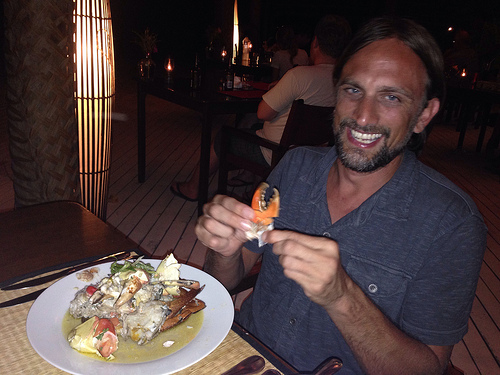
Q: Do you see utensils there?
A: Yes, there are utensils.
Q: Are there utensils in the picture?
A: Yes, there are utensils.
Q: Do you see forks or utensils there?
A: Yes, there are utensils.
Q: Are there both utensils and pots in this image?
A: No, there are utensils but no pots.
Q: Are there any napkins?
A: No, there are no napkins.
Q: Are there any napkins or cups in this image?
A: No, there are no napkins or cups.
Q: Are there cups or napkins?
A: No, there are no napkins or cups.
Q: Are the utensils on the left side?
A: Yes, the utensils are on the left of the image.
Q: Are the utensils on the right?
A: No, the utensils are on the left of the image.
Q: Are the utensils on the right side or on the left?
A: The utensils are on the left of the image.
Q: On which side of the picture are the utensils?
A: The utensils are on the left of the image.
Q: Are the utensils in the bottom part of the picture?
A: Yes, the utensils are in the bottom of the image.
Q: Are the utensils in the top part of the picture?
A: No, the utensils are in the bottom of the image.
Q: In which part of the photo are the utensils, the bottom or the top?
A: The utensils are in the bottom of the image.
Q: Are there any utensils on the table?
A: Yes, there are utensils on the table.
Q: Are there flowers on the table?
A: No, there are utensils on the table.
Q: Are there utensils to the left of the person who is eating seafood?
A: Yes, there are utensils to the left of the man.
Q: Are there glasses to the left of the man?
A: No, there are utensils to the left of the man.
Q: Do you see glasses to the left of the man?
A: No, there are utensils to the left of the man.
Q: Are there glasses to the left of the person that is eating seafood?
A: No, there are utensils to the left of the man.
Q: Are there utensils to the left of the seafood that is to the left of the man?
A: Yes, there are utensils to the left of the seafood.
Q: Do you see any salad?
A: No, there is no salad.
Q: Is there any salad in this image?
A: No, there is no salad.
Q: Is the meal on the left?
A: Yes, the meal is on the left of the image.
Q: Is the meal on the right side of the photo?
A: No, the meal is on the left of the image.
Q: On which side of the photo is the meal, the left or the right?
A: The meal is on the left of the image.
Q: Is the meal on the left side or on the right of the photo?
A: The meal is on the left of the image.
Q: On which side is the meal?
A: The meal is on the left of the image.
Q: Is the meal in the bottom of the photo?
A: Yes, the meal is in the bottom of the image.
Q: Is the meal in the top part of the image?
A: No, the meal is in the bottom of the image.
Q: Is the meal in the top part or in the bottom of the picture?
A: The meal is in the bottom of the image.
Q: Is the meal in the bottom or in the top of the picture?
A: The meal is in the bottom of the image.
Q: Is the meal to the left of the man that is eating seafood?
A: Yes, the meal is to the left of the man.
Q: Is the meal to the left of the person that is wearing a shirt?
A: Yes, the meal is to the left of the man.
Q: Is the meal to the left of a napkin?
A: No, the meal is to the left of the man.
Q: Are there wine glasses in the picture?
A: No, there are no wine glasses.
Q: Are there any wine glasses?
A: No, there are no wine glasses.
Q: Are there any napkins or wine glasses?
A: No, there are no wine glasses or napkins.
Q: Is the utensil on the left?
A: Yes, the utensil is on the left of the image.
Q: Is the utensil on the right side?
A: No, the utensil is on the left of the image.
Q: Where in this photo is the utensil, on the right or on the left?
A: The utensil is on the left of the image.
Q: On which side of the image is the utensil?
A: The utensil is on the left of the image.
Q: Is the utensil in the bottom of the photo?
A: Yes, the utensil is in the bottom of the image.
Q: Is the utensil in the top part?
A: No, the utensil is in the bottom of the image.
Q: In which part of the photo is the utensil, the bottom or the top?
A: The utensil is in the bottom of the image.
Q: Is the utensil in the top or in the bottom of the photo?
A: The utensil is in the bottom of the image.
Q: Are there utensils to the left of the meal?
A: Yes, there is a utensil to the left of the meal.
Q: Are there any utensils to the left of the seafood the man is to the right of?
A: Yes, there is a utensil to the left of the seafood.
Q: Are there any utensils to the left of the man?
A: Yes, there is a utensil to the left of the man.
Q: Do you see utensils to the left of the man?
A: Yes, there is a utensil to the left of the man.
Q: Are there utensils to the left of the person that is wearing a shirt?
A: Yes, there is a utensil to the left of the man.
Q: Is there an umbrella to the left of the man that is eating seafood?
A: No, there is a utensil to the left of the man.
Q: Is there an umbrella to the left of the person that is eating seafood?
A: No, there is a utensil to the left of the man.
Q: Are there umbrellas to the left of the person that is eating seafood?
A: No, there is a utensil to the left of the man.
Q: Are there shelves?
A: No, there are no shelves.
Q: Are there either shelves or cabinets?
A: No, there are no shelves or cabinets.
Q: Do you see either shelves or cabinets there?
A: No, there are no shelves or cabinets.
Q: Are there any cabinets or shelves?
A: No, there are no shelves or cabinets.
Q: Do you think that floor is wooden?
A: Yes, the floor is wooden.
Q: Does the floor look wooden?
A: Yes, the floor is wooden.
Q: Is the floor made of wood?
A: Yes, the floor is made of wood.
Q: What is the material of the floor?
A: The floor is made of wood.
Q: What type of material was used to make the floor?
A: The floor is made of wood.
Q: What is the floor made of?
A: The floor is made of wood.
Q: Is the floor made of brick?
A: No, the floor is made of wood.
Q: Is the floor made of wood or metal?
A: The floor is made of wood.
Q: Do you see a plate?
A: Yes, there is a plate.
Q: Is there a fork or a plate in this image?
A: Yes, there is a plate.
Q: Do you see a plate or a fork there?
A: Yes, there is a plate.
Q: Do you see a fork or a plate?
A: Yes, there is a plate.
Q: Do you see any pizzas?
A: No, there are no pizzas.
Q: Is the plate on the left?
A: Yes, the plate is on the left of the image.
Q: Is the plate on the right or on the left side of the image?
A: The plate is on the left of the image.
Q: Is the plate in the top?
A: No, the plate is in the bottom of the image.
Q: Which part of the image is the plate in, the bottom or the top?
A: The plate is in the bottom of the image.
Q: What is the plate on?
A: The plate is on the table.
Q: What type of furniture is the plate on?
A: The plate is on the table.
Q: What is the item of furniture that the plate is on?
A: The piece of furniture is a table.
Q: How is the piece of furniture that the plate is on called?
A: The piece of furniture is a table.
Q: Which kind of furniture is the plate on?
A: The plate is on the table.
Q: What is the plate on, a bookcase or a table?
A: The plate is on a table.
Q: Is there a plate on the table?
A: Yes, there is a plate on the table.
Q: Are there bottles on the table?
A: No, there is a plate on the table.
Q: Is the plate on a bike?
A: No, the plate is on the table.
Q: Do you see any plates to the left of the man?
A: Yes, there is a plate to the left of the man.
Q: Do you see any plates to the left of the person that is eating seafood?
A: Yes, there is a plate to the left of the man.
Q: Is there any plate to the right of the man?
A: No, the plate is to the left of the man.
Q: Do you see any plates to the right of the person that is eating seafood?
A: No, the plate is to the left of the man.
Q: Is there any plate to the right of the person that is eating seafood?
A: No, the plate is to the left of the man.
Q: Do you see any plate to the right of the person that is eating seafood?
A: No, the plate is to the left of the man.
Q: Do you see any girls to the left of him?
A: No, there is a plate to the left of the man.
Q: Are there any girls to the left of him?
A: No, there is a plate to the left of the man.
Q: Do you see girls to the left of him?
A: No, there is a plate to the left of the man.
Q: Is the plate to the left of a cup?
A: No, the plate is to the left of the man.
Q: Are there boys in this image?
A: No, there are no boys.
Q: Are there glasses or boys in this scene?
A: No, there are no boys or glasses.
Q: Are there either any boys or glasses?
A: No, there are no boys or glasses.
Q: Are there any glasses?
A: No, there are no glasses.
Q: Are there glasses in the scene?
A: No, there are no glasses.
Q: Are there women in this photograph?
A: No, there are no women.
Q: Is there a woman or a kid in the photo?
A: No, there are no women or children.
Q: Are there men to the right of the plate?
A: Yes, there is a man to the right of the plate.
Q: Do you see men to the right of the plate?
A: Yes, there is a man to the right of the plate.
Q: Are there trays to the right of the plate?
A: No, there is a man to the right of the plate.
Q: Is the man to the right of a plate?
A: Yes, the man is to the right of a plate.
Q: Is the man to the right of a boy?
A: No, the man is to the right of a plate.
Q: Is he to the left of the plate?
A: No, the man is to the right of the plate.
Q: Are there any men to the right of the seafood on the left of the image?
A: Yes, there is a man to the right of the seafood.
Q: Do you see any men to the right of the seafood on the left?
A: Yes, there is a man to the right of the seafood.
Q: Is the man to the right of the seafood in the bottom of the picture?
A: Yes, the man is to the right of the seafood.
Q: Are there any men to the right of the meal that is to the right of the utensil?
A: Yes, there is a man to the right of the meal.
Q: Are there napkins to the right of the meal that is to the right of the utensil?
A: No, there is a man to the right of the meal.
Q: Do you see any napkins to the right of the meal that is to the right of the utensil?
A: No, there is a man to the right of the meal.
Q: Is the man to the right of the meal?
A: Yes, the man is to the right of the meal.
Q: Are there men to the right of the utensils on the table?
A: Yes, there is a man to the right of the utensils.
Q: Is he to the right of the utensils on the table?
A: Yes, the man is to the right of the utensils.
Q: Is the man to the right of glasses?
A: No, the man is to the right of the utensils.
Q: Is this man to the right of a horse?
A: No, the man is to the right of the utensil.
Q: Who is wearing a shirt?
A: The man is wearing a shirt.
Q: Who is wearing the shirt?
A: The man is wearing a shirt.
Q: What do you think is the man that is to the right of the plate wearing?
A: The man is wearing a shirt.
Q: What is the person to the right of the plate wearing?
A: The man is wearing a shirt.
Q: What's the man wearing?
A: The man is wearing a shirt.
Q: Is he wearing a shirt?
A: Yes, the man is wearing a shirt.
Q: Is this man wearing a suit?
A: No, the man is wearing a shirt.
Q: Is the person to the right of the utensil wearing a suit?
A: No, the man is wearing a shirt.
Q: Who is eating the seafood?
A: The man is eating the seafood.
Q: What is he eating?
A: The man is eating seafood.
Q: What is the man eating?
A: The man is eating seafood.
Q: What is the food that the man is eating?
A: The food is seafood.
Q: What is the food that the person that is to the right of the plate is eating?
A: The food is seafood.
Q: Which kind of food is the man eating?
A: The man is eating seafood.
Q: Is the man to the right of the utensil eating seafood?
A: Yes, the man is eating seafood.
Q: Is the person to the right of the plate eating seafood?
A: Yes, the man is eating seafood.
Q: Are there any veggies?
A: No, there are no veggies.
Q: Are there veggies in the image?
A: No, there are no veggies.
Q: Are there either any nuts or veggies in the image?
A: No, there are no veggies or nuts.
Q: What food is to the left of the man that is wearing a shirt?
A: The food is seafood.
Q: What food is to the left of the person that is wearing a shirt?
A: The food is seafood.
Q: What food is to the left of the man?
A: The food is seafood.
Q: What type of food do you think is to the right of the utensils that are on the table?
A: The food is seafood.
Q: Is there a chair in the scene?
A: Yes, there is a chair.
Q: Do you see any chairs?
A: Yes, there is a chair.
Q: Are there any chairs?
A: Yes, there is a chair.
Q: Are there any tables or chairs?
A: Yes, there is a chair.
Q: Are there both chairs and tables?
A: Yes, there are both a chair and a table.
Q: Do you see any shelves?
A: No, there are no shelves.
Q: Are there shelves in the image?
A: No, there are no shelves.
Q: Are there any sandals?
A: Yes, there are sandals.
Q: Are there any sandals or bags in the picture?
A: Yes, there are sandals.